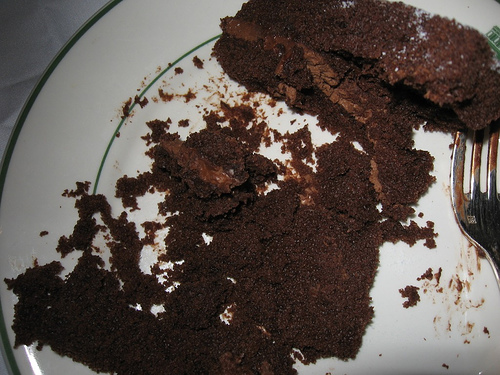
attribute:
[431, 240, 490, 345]
smear — chocolate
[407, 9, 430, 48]
powder — white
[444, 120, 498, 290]
fork — silver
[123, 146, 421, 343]
cake — chocolate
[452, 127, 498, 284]
fork — silver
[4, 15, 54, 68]
tablecloth — white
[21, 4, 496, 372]
chocolate cake — smashed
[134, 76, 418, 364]
cake — chocolate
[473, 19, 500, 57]
design — green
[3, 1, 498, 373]
cake — chocolate, moist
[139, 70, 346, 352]
cake — brown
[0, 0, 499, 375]
plate — white, round, white and green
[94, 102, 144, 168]
marking — green